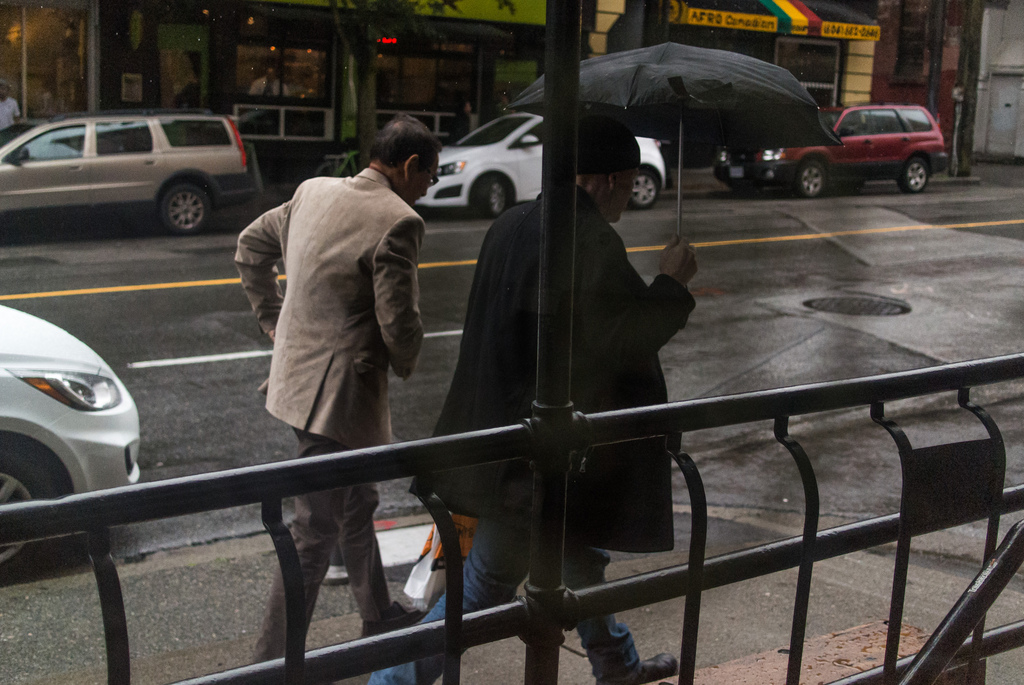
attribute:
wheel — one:
[1, 435, 88, 576]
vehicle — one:
[5, 292, 155, 588]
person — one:
[431, 46, 758, 680]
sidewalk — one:
[119, 536, 878, 681]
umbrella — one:
[577, 29, 833, 306]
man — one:
[463, 83, 697, 604]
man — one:
[476, 130, 680, 681]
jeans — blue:
[426, 482, 681, 670]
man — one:
[463, 145, 693, 649]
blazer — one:
[225, 158, 403, 452]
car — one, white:
[7, 264, 155, 554]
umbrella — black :
[529, 5, 934, 170]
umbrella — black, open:
[480, 44, 839, 157]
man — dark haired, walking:
[210, 95, 502, 471]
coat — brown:
[243, 225, 395, 364]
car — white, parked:
[401, 78, 719, 228]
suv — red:
[720, 117, 1004, 208]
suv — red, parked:
[722, 89, 1012, 234]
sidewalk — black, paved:
[258, 459, 864, 676]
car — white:
[0, 340, 243, 537]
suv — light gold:
[20, 24, 280, 206]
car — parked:
[0, 318, 204, 474]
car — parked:
[14, 117, 270, 273]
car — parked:
[401, 122, 691, 272]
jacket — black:
[401, 219, 713, 546]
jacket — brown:
[230, 163, 423, 449]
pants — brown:
[252, 430, 425, 657]